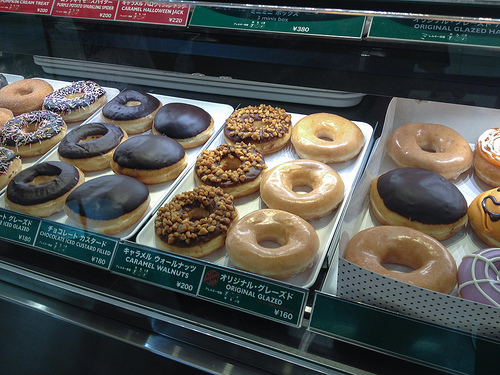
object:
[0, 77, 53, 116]
donut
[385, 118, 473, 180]
donuts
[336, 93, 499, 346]
box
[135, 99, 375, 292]
tray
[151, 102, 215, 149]
donuts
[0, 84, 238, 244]
tray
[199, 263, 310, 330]
sign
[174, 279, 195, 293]
prices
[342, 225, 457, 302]
doughnuts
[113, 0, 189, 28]
sign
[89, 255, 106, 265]
prices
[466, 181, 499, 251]
doughnut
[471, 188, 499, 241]
frosting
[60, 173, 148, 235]
doughnut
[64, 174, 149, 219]
creme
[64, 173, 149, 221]
frosting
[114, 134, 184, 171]
frosting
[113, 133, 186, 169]
creme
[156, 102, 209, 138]
frosting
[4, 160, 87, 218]
doughnut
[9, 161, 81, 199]
frosting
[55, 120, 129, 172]
doughnut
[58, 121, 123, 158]
frosting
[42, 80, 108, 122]
doughnut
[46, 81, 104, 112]
frosting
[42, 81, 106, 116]
sprinkles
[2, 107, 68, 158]
doughnut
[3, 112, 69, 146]
frosting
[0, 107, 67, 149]
sprinkles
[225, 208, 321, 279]
doughnut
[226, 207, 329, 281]
glaze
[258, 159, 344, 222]
doughnut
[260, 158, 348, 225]
glaze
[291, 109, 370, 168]
glaze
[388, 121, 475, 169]
glaze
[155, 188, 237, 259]
doughnut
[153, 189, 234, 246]
frosting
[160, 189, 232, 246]
nuts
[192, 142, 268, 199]
doughnut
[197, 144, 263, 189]
frosting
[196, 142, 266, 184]
nuts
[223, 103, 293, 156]
doughnut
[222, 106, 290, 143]
frosting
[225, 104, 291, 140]
nuts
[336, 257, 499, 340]
design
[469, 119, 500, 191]
donut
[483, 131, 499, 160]
caramel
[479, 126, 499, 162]
walnuts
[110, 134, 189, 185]
donut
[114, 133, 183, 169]
icing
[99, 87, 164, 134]
donut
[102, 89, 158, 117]
glaze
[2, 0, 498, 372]
case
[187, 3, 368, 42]
placard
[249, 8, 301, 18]
title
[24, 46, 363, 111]
tray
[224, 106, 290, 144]
icing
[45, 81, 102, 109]
icing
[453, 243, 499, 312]
donut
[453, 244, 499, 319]
frosting